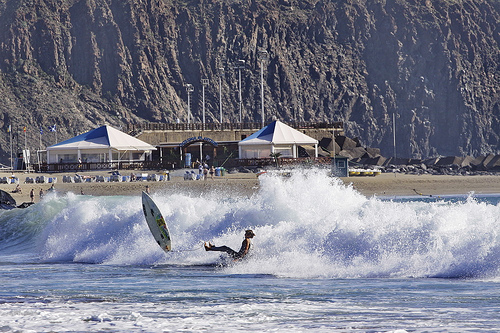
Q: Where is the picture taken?
A: The beach.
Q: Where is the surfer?
A: Ocean.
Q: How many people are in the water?
A: One.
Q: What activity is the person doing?
A: Surfing.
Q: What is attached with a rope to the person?
A: Surfboard.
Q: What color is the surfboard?
A: White.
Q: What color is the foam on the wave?
A: White.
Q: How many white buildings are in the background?
A: Two.